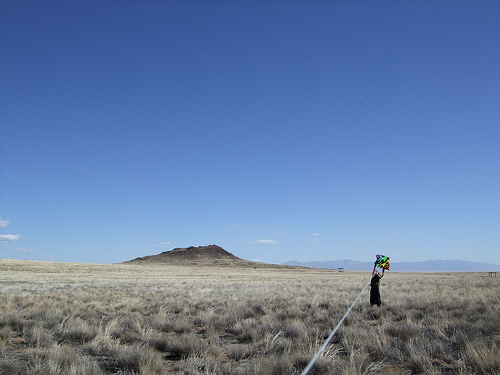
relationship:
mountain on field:
[125, 230, 236, 281] [50, 278, 232, 362]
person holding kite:
[363, 246, 400, 324] [373, 250, 393, 275]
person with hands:
[363, 246, 400, 324] [368, 267, 388, 280]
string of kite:
[299, 345, 337, 360] [373, 250, 393, 275]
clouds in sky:
[3, 194, 32, 257] [463, 11, 485, 23]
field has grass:
[50, 278, 232, 362] [455, 304, 488, 346]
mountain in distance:
[125, 230, 236, 281] [297, 115, 306, 118]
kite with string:
[373, 250, 393, 275] [299, 345, 337, 360]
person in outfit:
[363, 246, 400, 324] [368, 276, 387, 309]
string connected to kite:
[299, 345, 337, 360] [373, 250, 393, 275]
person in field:
[363, 246, 400, 324] [50, 278, 232, 362]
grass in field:
[455, 304, 488, 346] [50, 278, 232, 362]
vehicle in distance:
[334, 258, 347, 275] [297, 115, 306, 118]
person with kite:
[363, 246, 400, 324] [373, 250, 393, 275]